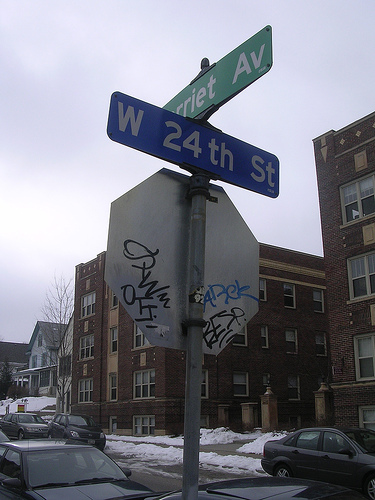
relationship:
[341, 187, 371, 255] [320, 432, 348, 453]
window building window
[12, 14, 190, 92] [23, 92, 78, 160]
white clouds in sky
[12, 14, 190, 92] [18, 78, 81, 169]
white clouds in sky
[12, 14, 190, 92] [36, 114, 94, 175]
white clouds in sky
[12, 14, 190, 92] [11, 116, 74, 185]
white clouds in sky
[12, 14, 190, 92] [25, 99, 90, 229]
white clouds in sky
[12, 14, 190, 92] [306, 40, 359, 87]
white clouds in sky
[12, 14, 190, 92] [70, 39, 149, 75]
white clouds in sky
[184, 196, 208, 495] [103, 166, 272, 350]
pole on sign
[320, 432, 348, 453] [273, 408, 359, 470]
window on car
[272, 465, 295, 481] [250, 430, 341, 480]
tire on car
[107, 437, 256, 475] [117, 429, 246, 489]
snow on ground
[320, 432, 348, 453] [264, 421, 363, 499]
window on car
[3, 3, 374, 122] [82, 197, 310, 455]
sky above building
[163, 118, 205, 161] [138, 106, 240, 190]
number on sign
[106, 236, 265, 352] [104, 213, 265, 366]
writing on sign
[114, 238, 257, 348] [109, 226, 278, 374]
grafitti on sign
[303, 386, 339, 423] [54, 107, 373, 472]
stone columns in front of building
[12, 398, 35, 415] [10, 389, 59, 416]
sign in yard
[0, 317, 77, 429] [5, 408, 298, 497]
houses lining street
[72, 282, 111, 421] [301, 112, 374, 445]
windows on building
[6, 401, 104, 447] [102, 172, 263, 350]
cars parked by back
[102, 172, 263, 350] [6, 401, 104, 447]
back on cars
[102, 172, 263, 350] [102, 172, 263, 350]
back on back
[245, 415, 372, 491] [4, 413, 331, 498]
car in street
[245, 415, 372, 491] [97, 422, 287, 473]
car parked in snow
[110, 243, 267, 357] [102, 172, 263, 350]
graffiti on back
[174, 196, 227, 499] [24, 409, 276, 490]
pole near street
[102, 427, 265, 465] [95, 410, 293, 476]
sidewalk covered in snow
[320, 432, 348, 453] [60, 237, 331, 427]
window on building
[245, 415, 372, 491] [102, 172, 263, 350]
car parked back